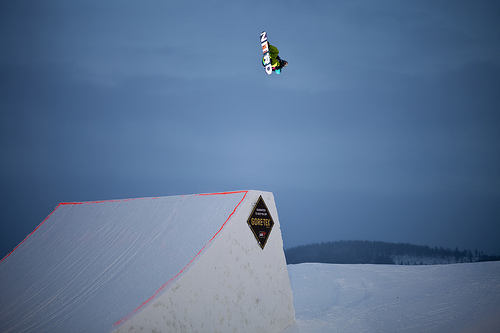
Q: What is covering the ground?
A: Snow.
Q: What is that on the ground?
A: Ski ramp.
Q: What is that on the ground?
A: Snowy slope.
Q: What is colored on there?
A: Pink ramp edges.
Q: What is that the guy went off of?
A: Snow ramp.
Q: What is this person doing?
A: Snowboarding.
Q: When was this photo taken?
A: Evening time.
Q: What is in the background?
A: Trees.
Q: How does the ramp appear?
A: Covered in snow.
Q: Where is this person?
A: In the sky.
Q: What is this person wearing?
A: Snow gear.